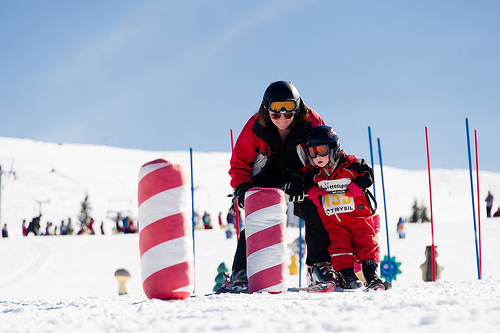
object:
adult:
[228, 78, 348, 294]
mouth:
[315, 159, 324, 165]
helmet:
[263, 81, 303, 107]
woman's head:
[257, 80, 303, 131]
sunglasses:
[270, 112, 298, 121]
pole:
[367, 125, 375, 201]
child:
[298, 126, 386, 291]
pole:
[378, 137, 393, 282]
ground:
[0, 216, 498, 333]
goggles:
[268, 97, 296, 112]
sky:
[0, 0, 499, 174]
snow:
[0, 219, 499, 332]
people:
[22, 218, 28, 234]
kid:
[296, 124, 386, 292]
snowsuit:
[303, 154, 380, 271]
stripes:
[140, 211, 185, 262]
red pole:
[427, 126, 437, 282]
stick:
[458, 117, 483, 279]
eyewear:
[309, 145, 331, 157]